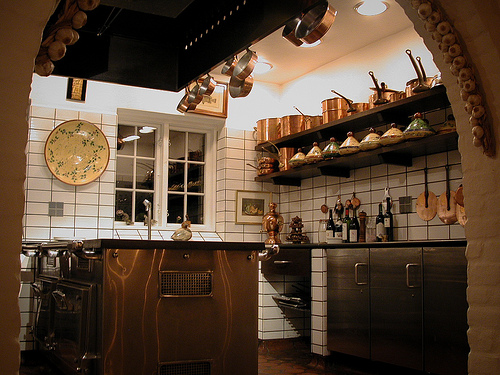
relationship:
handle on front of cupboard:
[404, 262, 416, 289] [371, 246, 425, 374]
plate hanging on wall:
[44, 118, 110, 186] [19, 70, 284, 351]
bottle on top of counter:
[383, 196, 394, 243] [278, 240, 465, 250]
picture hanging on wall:
[235, 188, 274, 227] [19, 70, 284, 351]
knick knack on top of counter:
[170, 220, 193, 241] [22, 239, 267, 251]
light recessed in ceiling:
[353, 1, 391, 17] [207, 0, 413, 87]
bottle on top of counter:
[376, 201, 385, 240] [278, 240, 465, 250]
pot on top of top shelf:
[254, 117, 282, 143] [255, 85, 451, 151]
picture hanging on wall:
[183, 77, 229, 118] [19, 70, 284, 351]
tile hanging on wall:
[74, 191, 99, 206] [19, 70, 284, 351]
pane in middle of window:
[135, 157, 155, 190] [114, 115, 220, 233]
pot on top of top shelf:
[281, 114, 314, 139] [255, 85, 451, 151]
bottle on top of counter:
[349, 207, 359, 242] [278, 240, 465, 250]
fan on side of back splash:
[415, 166, 439, 221] [283, 144, 465, 242]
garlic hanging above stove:
[34, 0, 100, 77] [19, 238, 265, 375]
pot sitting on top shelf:
[293, 105, 322, 130] [255, 85, 451, 151]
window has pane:
[114, 115, 220, 233] [135, 157, 155, 190]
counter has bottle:
[278, 240, 465, 250] [383, 196, 394, 243]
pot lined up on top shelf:
[254, 117, 282, 143] [255, 85, 451, 151]